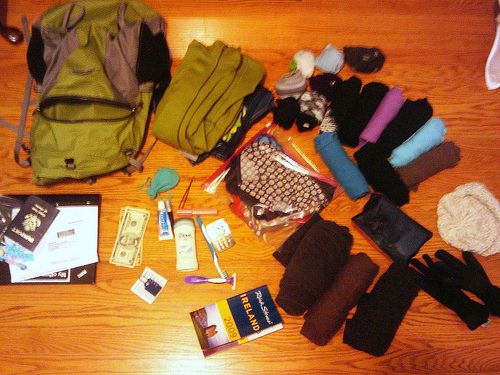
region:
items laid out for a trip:
[2, 3, 498, 373]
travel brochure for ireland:
[183, 289, 283, 357]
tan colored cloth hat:
[431, 174, 498, 261]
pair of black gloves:
[415, 249, 499, 339]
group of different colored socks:
[361, 73, 473, 186]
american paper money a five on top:
[103, 192, 156, 272]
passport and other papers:
[4, 190, 105, 301]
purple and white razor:
[182, 270, 244, 295]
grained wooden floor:
[2, 293, 190, 374]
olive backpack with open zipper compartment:
[10, 4, 172, 191]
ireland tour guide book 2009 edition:
[188, 284, 285, 361]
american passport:
[3, 191, 60, 252]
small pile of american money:
[110, 203, 150, 270]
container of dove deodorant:
[171, 215, 200, 272]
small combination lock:
[137, 270, 160, 297]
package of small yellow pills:
[204, 218, 235, 253]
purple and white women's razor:
[181, 269, 239, 291]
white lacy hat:
[433, 179, 499, 259]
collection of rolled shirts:
[312, 73, 463, 202]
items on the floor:
[5, 6, 496, 373]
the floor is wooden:
[240, 5, 497, 65]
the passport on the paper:
[7, 196, 59, 254]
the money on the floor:
[106, 200, 155, 270]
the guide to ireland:
[175, 283, 280, 358]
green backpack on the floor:
[5, 0, 145, 187]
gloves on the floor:
[407, 253, 499, 322]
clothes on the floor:
[327, 78, 462, 195]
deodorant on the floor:
[170, 216, 214, 268]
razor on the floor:
[182, 268, 240, 293]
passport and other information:
[5, 195, 105, 281]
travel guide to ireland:
[196, 281, 270, 351]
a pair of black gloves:
[407, 249, 489, 319]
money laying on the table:
[112, 205, 149, 274]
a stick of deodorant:
[172, 216, 204, 273]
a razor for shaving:
[185, 272, 245, 287]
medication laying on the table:
[211, 218, 236, 256]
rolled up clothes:
[311, 65, 470, 217]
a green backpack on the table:
[13, 8, 163, 183]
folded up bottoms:
[167, 41, 264, 173]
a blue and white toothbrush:
[193, 213, 231, 282]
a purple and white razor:
[183, 271, 238, 288]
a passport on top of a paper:
[1, 191, 63, 254]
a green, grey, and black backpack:
[7, 2, 170, 182]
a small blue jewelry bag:
[139, 163, 184, 203]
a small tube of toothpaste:
[153, 196, 176, 245]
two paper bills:
[106, 201, 149, 274]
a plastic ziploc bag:
[201, 117, 345, 252]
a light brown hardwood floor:
[1, 0, 498, 373]